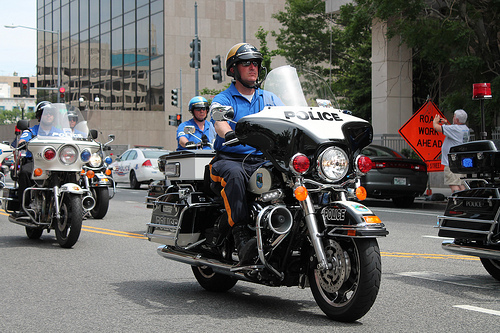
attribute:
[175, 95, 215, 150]
policeman — parading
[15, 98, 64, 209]
policeman — parading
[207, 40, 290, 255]
policeman — parading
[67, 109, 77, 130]
policeman — parading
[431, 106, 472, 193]
man — photographing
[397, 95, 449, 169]
sign — diamond-shaped, orange, construction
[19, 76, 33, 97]
light — traffic, red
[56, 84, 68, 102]
light — traffic, red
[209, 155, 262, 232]
pants — blue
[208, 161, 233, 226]
stripe — orange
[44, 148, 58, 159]
light — red, headlight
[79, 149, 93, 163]
light — blue, headlight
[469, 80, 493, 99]
light — red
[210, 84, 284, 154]
shirt — blue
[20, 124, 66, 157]
shirt — blue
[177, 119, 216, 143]
shirt — blue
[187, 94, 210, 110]
helmet — blue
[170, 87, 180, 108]
light — traffic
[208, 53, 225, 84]
light — traffic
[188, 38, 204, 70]
light — traffic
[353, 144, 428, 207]
car — parked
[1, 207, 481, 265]
line — yellow, double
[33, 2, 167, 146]
wall — glass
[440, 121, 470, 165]
shirt — gray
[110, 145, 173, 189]
car — police, parked